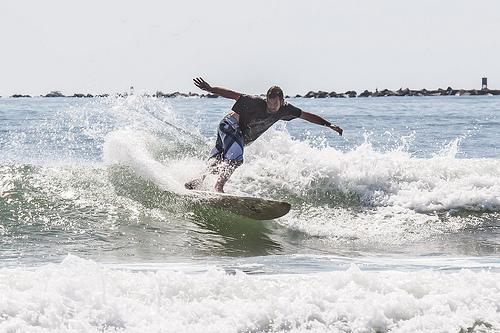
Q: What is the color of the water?
A: Blue.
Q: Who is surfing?
A: A man.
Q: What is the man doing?
A: Surfing.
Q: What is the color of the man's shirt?
A: Black.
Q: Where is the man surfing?
A: On the water.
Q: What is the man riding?
A: A surfboard.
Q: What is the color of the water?
A: Blue.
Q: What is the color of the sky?
A: Gray.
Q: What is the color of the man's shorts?
A: Purple.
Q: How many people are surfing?
A: One.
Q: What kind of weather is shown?
A: Sunny.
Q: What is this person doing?
A: Surfing.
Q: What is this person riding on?
A: A surfboard.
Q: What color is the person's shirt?
A: Black.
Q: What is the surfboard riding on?
A: A wave.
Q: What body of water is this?
A: The ocean.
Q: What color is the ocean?
A: Blue.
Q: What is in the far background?
A: A line of rocks.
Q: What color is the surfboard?
A: Cream colored.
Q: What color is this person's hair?
A: Brown.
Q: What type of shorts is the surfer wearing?
A: Patterned shorts.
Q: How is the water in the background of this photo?
A: Still.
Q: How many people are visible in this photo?
A: One.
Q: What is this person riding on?
A: A surfboard.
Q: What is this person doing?
A: Surfing.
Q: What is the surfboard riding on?
A: A wave.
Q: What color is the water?
A: Blue.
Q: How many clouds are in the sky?
A: None.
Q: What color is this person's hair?
A: Brown.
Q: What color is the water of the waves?
A: White.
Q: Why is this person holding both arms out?
A: For balance.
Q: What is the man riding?
A: Surfboard.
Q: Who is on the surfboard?
A: A man.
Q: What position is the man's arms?
A: Open.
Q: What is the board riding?
A: Wave.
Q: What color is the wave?
A: White.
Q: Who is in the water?
A: A man.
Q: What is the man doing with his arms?
A: Holding them out.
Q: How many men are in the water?
A: One.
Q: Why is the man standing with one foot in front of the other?
A: For balance.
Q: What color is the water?
A: Blue.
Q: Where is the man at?
A: In water.